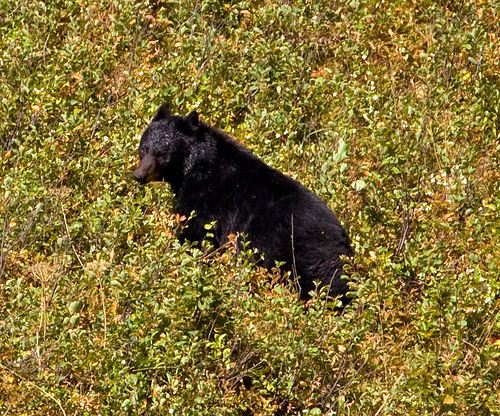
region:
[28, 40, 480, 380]
Day time picture.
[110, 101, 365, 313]
Bear is between the plants.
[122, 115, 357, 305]
Bear is black color.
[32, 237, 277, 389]
Plants are green and brown color.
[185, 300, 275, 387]
Stems are brown color.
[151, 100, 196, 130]
Ears are black color.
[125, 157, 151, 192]
Nose is black color.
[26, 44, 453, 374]
Picture is taken in outdoor.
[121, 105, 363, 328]
Bear is sitting.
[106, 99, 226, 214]
Bear is looking to left side.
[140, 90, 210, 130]
Two ears for bear.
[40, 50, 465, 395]
Picture is taken outdoor.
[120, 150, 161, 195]
Nose is black color.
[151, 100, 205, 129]
ears are black color.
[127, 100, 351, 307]
black dog in field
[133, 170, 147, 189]
little black nose of dog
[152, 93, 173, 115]
right ear of black dog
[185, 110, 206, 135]
left ear of black dog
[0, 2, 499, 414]
green and short grass in a field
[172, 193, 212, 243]
two front legs of black dog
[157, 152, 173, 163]
small black left eye of dog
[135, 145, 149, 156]
small black right eye of dog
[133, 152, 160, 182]
little trunk of black dog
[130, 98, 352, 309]
black dog lying in a field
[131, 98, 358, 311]
black bear is surrounded by shrubs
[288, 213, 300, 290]
thin twig in front of bear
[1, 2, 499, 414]
prickly shrubs engulfing bear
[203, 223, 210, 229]
green leaf in front of bear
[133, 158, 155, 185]
bear has a long brown snout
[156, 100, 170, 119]
pointy ear to the left of ear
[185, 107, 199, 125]
ear to the right of ear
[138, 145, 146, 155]
bear has a right eye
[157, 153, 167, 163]
bear has a left eye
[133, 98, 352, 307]
bear is furry